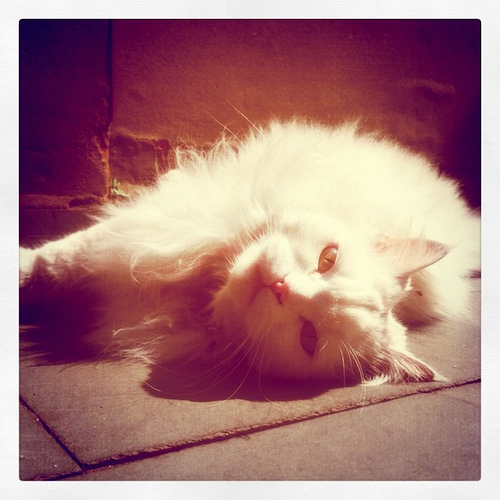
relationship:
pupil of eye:
[323, 257, 337, 263] [317, 242, 337, 270]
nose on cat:
[271, 274, 298, 309] [20, 110, 483, 391]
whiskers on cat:
[192, 196, 296, 418] [20, 110, 483, 391]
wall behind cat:
[24, 24, 489, 264] [20, 110, 483, 391]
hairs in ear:
[376, 214, 432, 266] [362, 235, 447, 280]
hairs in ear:
[362, 356, 426, 390] [366, 348, 433, 385]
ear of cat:
[362, 235, 447, 280] [20, 110, 483, 391]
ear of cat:
[366, 348, 433, 385] [20, 110, 483, 391]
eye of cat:
[312, 239, 345, 277] [20, 110, 483, 391]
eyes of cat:
[300, 320, 319, 357] [20, 110, 483, 391]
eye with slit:
[312, 239, 345, 277] [322, 254, 335, 266]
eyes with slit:
[300, 320, 319, 357] [301, 329, 318, 340]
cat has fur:
[20, 110, 483, 391] [256, 164, 353, 214]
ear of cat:
[366, 345, 456, 390] [20, 110, 483, 391]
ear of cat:
[361, 234, 462, 299] [20, 110, 483, 391]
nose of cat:
[271, 274, 290, 306] [20, 110, 483, 391]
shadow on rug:
[12, 310, 356, 411] [22, 320, 483, 475]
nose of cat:
[271, 274, 290, 306] [149, 110, 408, 375]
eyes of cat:
[294, 244, 354, 370] [20, 110, 483, 391]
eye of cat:
[317, 243, 340, 274] [20, 110, 483, 391]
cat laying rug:
[20, 110, 483, 391] [56, 352, 249, 430]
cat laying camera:
[20, 120, 482, 384] [197, 223, 413, 363]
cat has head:
[20, 110, 483, 391] [199, 206, 457, 406]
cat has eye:
[20, 110, 483, 391] [307, 237, 347, 280]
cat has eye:
[20, 110, 483, 391] [286, 314, 328, 364]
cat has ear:
[20, 120, 482, 384] [369, 228, 455, 289]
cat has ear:
[20, 120, 482, 384] [350, 341, 461, 401]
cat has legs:
[20, 120, 482, 384] [18, 206, 149, 357]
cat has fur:
[20, 110, 483, 391] [48, 96, 480, 249]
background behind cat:
[20, 18, 481, 264] [20, 120, 482, 384]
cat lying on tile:
[20, 120, 482, 384] [19, 272, 479, 465]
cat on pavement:
[20, 110, 483, 391] [24, 259, 478, 480]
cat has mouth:
[20, 110, 483, 391] [246, 250, 266, 295]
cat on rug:
[20, 110, 483, 391] [17, 386, 477, 475]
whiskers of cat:
[186, 321, 275, 410] [20, 110, 483, 391]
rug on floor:
[22, 287, 480, 466] [16, 211, 478, 476]